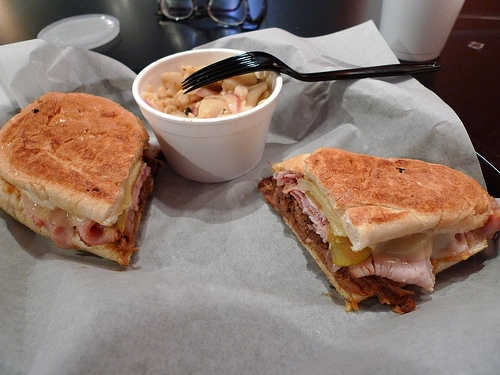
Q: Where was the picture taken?
A: In a restaurant.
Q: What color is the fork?
A: Black.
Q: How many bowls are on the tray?
A: 1.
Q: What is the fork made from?
A: Plastic.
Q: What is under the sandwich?
A: Paper.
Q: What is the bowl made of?
A: Styrofoam.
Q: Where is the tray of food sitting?
A: At a table.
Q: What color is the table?
A: Brown.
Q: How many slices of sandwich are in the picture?
A: 2.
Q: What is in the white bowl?
A: Pasta salad.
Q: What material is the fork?
A: Plastic.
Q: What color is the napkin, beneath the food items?
A: White.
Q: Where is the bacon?
A: Inside the sandwich halves.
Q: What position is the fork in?
A: It's upside down.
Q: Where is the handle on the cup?
A: There is none.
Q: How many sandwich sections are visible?
A: Two.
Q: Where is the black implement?
A: Resting on the white cup.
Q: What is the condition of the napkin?
A: It is bunched and wrinkled.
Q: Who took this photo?
A: The person who is going to eat.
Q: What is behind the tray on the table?
A: A pair of eye glasses.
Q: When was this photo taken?
A: At meal time.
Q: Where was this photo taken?
A: In a restaurant.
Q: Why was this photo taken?
A: To show how delicious all the food looks.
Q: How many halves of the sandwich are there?
A: There are 2.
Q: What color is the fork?
A: It is black.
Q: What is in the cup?
A: A type of pasta.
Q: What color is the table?
A: It is black.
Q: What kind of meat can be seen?
A: Turkey and bacon.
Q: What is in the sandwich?
A: Several meats.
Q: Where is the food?
A: On a paper.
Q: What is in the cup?
A: Macaroni salad.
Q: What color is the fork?
A: Black.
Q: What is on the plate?
A: Parchment paper.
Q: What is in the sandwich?
A: Cheese.